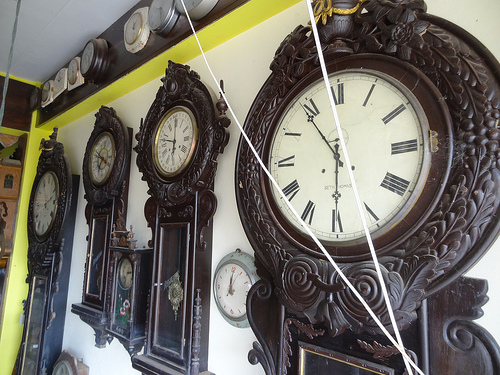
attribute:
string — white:
[178, 0, 429, 375]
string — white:
[302, 0, 416, 375]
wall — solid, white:
[50, 1, 499, 375]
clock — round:
[144, 1, 184, 39]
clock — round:
[120, 3, 154, 55]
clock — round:
[76, 36, 113, 83]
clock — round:
[62, 55, 87, 93]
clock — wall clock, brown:
[232, 1, 498, 375]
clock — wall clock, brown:
[127, 54, 235, 375]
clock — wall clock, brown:
[69, 99, 139, 352]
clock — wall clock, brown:
[12, 122, 85, 375]